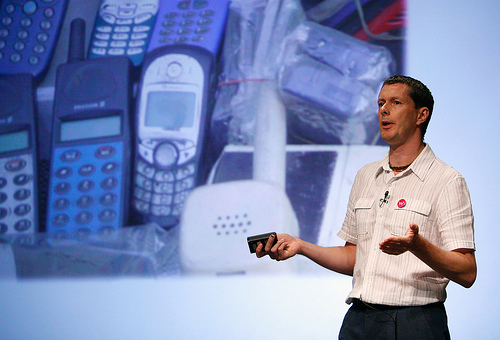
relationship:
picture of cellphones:
[1, 1, 412, 284] [5, 2, 397, 270]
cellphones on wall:
[5, 2, 397, 270] [0, 0, 497, 339]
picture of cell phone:
[1, 1, 412, 284] [129, 41, 214, 232]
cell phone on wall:
[129, 41, 214, 232] [0, 0, 497, 339]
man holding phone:
[252, 74, 477, 339] [242, 231, 277, 256]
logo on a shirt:
[397, 196, 407, 211] [337, 147, 474, 315]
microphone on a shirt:
[375, 187, 391, 209] [337, 147, 474, 315]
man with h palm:
[252, 74, 477, 339] [380, 229, 411, 241]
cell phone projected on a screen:
[129, 41, 214, 232] [3, 0, 405, 280]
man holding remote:
[252, 74, 477, 339] [243, 220, 287, 250]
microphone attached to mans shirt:
[375, 187, 391, 209] [334, 141, 478, 308]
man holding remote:
[252, 74, 477, 339] [247, 232, 279, 249]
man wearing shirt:
[252, 74, 477, 339] [341, 149, 470, 300]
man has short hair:
[231, 60, 478, 339] [370, 71, 437, 122]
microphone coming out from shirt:
[375, 188, 393, 212] [334, 141, 478, 308]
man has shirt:
[252, 74, 477, 339] [334, 141, 478, 308]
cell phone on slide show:
[129, 41, 214, 232] [0, 0, 406, 283]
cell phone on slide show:
[47, 17, 137, 247] [2, 0, 367, 292]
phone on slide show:
[224, 207, 290, 262] [0, 0, 406, 283]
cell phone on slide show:
[0, 69, 37, 255] [0, 0, 406, 283]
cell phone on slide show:
[129, 41, 214, 232] [1, 1, 408, 291]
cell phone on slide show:
[88, 2, 158, 62] [2, 0, 498, 337]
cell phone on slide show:
[147, 2, 230, 49] [2, 0, 498, 337]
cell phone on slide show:
[47, 17, 137, 247] [2, 0, 498, 337]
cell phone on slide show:
[0, 69, 38, 257] [2, 0, 498, 337]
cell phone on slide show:
[128, 38, 212, 233] [2, 0, 498, 337]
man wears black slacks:
[252, 74, 477, 339] [336, 296, 452, 338]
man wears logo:
[252, 74, 477, 339] [395, 198, 408, 208]